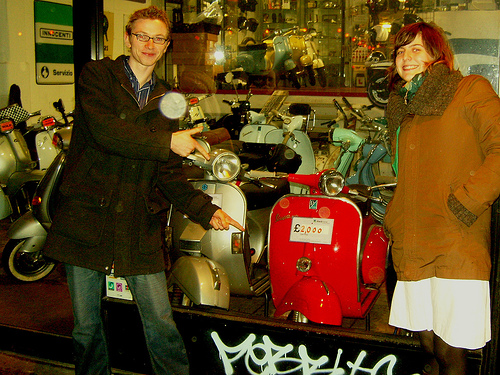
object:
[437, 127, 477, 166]
ground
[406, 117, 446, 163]
ground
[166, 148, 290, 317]
motorcycle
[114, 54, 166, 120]
collar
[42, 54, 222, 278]
black jacket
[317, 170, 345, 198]
headlight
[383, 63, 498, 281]
coat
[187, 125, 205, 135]
finger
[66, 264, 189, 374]
jeans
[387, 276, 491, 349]
short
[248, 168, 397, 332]
moped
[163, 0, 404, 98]
mirror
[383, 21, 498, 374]
people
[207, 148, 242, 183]
headlight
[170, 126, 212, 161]
hand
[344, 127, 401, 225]
motorcycle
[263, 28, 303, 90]
items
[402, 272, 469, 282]
edge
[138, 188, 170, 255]
pocket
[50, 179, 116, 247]
pocket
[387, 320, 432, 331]
edge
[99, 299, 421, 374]
panel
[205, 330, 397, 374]
graffiti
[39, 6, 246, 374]
man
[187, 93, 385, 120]
wall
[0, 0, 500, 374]
scooter store